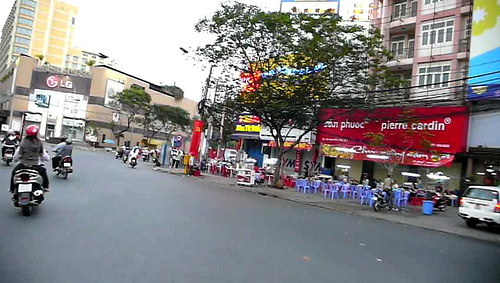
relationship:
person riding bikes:
[52, 136, 74, 174] [50, 150, 73, 179]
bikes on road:
[50, 150, 73, 179] [2, 142, 499, 279]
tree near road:
[177, 1, 409, 187] [119, 187, 243, 255]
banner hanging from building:
[317, 105, 469, 167] [310, 0, 472, 209]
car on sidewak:
[457, 185, 500, 228] [305, 198, 356, 211]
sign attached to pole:
[187, 117, 204, 158] [189, 49, 219, 176]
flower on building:
[470, 0, 498, 35] [320, 1, 496, 204]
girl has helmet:
[9, 121, 53, 196] [23, 123, 41, 139]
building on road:
[368, 0, 500, 197] [2, 142, 499, 279]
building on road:
[310, 0, 472, 209] [2, 142, 499, 279]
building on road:
[0, 52, 200, 158] [2, 142, 499, 279]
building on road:
[0, 1, 79, 70] [2, 142, 499, 279]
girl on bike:
[9, 125, 50, 191] [9, 165, 50, 216]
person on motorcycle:
[52, 139, 74, 170] [49, 152, 74, 178]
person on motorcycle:
[1, 128, 16, 155] [3, 143, 14, 166]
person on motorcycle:
[131, 138, 143, 166] [114, 106, 151, 179]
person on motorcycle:
[119, 145, 124, 150] [115, 149, 127, 157]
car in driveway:
[457, 185, 500, 228] [443, 202, 498, 239]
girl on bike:
[9, 125, 50, 191] [9, 140, 50, 215]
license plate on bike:
[17, 184, 31, 191] [10, 167, 43, 214]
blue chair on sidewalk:
[295, 178, 410, 207] [276, 186, 486, 218]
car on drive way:
[457, 185, 500, 228] [376, 204, 498, 249]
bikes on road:
[39, 105, 101, 230] [2, 142, 499, 279]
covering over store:
[310, 103, 470, 170] [321, 103, 467, 199]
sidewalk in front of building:
[277, 155, 463, 248] [310, 0, 472, 209]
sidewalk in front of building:
[277, 155, 463, 248] [227, 47, 320, 187]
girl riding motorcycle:
[9, 125, 50, 191] [8, 169, 48, 219]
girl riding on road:
[9, 125, 50, 191] [2, 142, 499, 279]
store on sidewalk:
[287, 82, 479, 210] [158, 162, 499, 241]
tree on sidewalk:
[177, 1, 409, 187] [158, 162, 499, 241]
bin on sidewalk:
[422, 200, 434, 215] [150, 150, 498, 248]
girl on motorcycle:
[9, 125, 50, 191] [12, 167, 42, 214]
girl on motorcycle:
[9, 125, 50, 191] [6, 148, 51, 203]